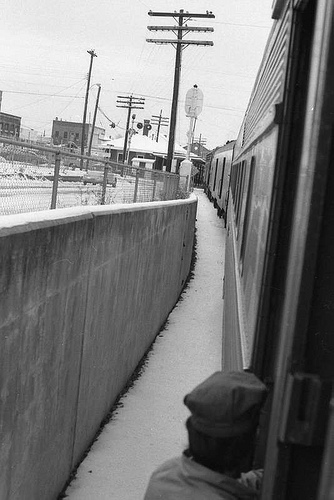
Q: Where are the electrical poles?
A: On the left side of the fence.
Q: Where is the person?
A: Leaning against the wall.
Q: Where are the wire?
A: On the telephone poles.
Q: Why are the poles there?
A: To hold wire.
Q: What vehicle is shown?
A: A train.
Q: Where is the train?
A: On the tracks.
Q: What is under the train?
A: A track.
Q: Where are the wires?
A: On the poles.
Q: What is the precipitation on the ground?
A: Snow.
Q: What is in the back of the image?
A: Buildings.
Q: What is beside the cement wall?
A: A chainlink fence.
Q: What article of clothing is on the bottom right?
A: A hat.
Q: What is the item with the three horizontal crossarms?
A: A telephone pole.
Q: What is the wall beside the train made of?
A: Cement.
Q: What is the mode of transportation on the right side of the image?
A: A train.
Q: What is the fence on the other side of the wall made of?
A: Chain Link.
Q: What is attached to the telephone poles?
A: Telephone lines.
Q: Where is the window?
A: On side of train.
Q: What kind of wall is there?
A: Cement wall with snow on top.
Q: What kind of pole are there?
A: Wooden electric pole.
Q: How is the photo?
A: Clear.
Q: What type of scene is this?
A: Outdoor.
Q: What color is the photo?
A: Black and white.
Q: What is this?
A: A train.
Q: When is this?
A: Daytime.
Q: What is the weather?
A: Cloudy.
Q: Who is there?
A: No one.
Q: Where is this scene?
A: Railway.